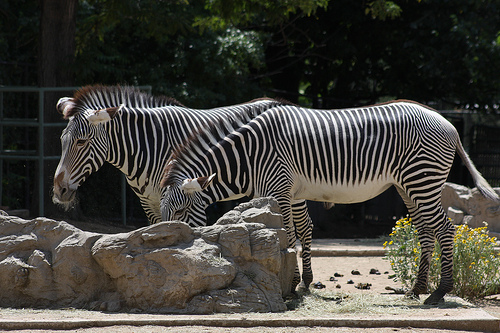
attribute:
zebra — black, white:
[156, 92, 495, 318]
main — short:
[68, 75, 190, 115]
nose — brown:
[49, 167, 69, 188]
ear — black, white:
[179, 174, 213, 195]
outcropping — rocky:
[8, 189, 288, 315]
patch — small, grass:
[333, 290, 414, 317]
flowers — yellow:
[388, 215, 492, 296]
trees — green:
[68, 7, 487, 95]